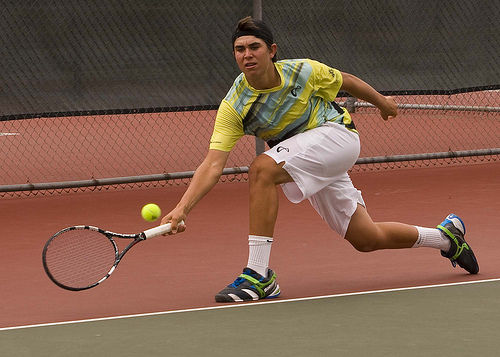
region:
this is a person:
[165, 10, 475, 318]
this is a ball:
[108, 170, 167, 234]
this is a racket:
[39, 183, 179, 298]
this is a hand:
[153, 75, 250, 254]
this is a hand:
[309, 49, 411, 133]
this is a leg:
[332, 170, 480, 282]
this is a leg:
[221, 122, 348, 308]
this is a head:
[204, 4, 293, 81]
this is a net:
[0, 7, 499, 173]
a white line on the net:
[34, 317, 106, 327]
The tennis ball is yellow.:
[141, 196, 162, 226]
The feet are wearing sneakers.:
[206, 213, 477, 303]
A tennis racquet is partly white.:
[41, 217, 184, 292]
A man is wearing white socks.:
[245, 221, 450, 277]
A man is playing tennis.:
[36, 21, 481, 302]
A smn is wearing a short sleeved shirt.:
[198, 55, 361, 155]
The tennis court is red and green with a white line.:
[1, 91, 494, 353]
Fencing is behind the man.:
[3, 0, 495, 196]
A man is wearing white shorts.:
[260, 120, 365, 238]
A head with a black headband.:
[229, 17, 279, 77]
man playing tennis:
[38, 16, 478, 301]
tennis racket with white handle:
[35, 221, 181, 286]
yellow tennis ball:
[137, 200, 159, 217]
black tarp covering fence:
[0, 0, 495, 110]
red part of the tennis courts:
[0, 87, 496, 317]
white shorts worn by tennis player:
[260, 120, 365, 235]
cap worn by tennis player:
[230, 12, 285, 42]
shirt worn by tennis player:
[201, 60, 356, 150]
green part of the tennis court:
[2, 280, 497, 350]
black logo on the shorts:
[275, 145, 290, 153]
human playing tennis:
[162, 15, 481, 302]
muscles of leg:
[246, 159, 280, 268]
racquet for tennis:
[39, 222, 191, 290]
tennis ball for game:
[138, 201, 161, 221]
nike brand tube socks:
[241, 233, 276, 246]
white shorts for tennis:
[266, 126, 363, 233]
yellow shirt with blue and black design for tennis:
[210, 60, 357, 145]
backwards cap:
[232, 17, 277, 39]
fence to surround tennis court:
[1, 3, 169, 183]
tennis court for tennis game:
[18, 302, 499, 355]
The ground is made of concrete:
[168, 309, 478, 351]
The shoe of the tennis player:
[209, 261, 283, 303]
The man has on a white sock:
[243, 230, 273, 274]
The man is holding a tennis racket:
[36, 211, 190, 298]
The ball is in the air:
[136, 197, 166, 225]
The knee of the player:
[239, 149, 289, 203]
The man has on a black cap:
[228, 10, 277, 47]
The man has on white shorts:
[259, 115, 378, 243]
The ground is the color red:
[4, 200, 49, 325]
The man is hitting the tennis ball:
[37, 12, 482, 330]